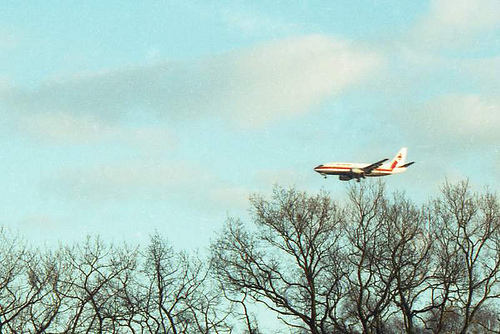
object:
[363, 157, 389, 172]
wing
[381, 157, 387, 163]
tip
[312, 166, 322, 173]
tip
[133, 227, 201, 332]
tree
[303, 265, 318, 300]
part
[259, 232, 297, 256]
branch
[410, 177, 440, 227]
ground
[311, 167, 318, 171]
nose tip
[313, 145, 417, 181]
airplane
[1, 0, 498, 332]
air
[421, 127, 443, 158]
ground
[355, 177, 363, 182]
wheel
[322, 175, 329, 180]
front wheel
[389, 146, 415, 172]
tail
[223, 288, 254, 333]
branch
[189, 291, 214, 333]
branch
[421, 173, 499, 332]
tree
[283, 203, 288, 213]
leaf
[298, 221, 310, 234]
leaf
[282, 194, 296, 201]
leaf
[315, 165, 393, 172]
line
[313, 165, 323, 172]
nose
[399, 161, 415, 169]
wing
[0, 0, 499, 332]
clouds